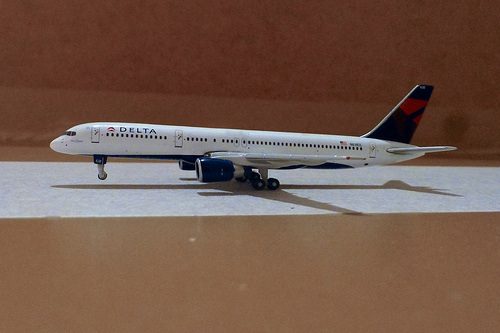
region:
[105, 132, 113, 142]
window on side of model plane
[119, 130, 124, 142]
window on side of model plane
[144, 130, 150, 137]
window on side of model plane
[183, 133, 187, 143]
window on side of model plane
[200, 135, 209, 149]
window on side of model plane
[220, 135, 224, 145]
window on side of model plane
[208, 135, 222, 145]
window on side of model plane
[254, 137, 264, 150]
window on side of model plane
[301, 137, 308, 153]
window on side of model plane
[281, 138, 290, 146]
window on side of model plane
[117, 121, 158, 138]
Delta writing on plane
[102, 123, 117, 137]
Delta symbol on plane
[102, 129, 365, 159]
Side windows on plane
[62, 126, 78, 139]
Front windows on plane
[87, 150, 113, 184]
Front wheel on plane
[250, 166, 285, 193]
Left wheel on plane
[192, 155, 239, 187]
Left engine on plane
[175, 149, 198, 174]
Right engine on plane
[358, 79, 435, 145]
Blue tail of plane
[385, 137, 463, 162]
Left tail wing of plane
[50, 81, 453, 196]
white airplane taking off from runway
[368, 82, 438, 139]
blue tailfin with red markings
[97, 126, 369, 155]
windows running along plane's side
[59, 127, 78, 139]
front windows of white plane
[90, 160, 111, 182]
wheels on front of plane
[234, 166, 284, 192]
wheels on middle of plane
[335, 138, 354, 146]
american flag painted on side of plane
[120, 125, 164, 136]
delta painted on side of plane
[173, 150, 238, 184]
blue engines of white plane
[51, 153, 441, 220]
shadow of airplane on runway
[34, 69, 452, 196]
a small model airplane.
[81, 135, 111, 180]
front landing gear.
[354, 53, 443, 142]
a wing on the back of a jet.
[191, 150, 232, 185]
a jet engine on a wing.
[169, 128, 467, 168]
a large wing on the left side of a plane.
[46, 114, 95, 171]
a cock pit on a jet.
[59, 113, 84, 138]
a window on a cock pit.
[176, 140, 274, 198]
A jet engine on a wing.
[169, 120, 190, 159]
a door on an airplane.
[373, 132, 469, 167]
a rear wing.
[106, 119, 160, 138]
DELTA jet logo painted on the plane's exterior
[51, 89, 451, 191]
a model airplane representing the DELTA airline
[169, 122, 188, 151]
One of the exit doors on the model airplane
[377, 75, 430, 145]
the large tail fin represented on the model airplane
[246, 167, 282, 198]
the wheels on the model airplane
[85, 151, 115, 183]
the front wheel of the model plane slightly off the ground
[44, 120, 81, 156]
the window which allows viewing from the cockpit area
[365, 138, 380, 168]
the rear exit door on the DELTA model airplane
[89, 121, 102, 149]
the front exit door on the DELTA model airplane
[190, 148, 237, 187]
One of the large jet engines represented on the model